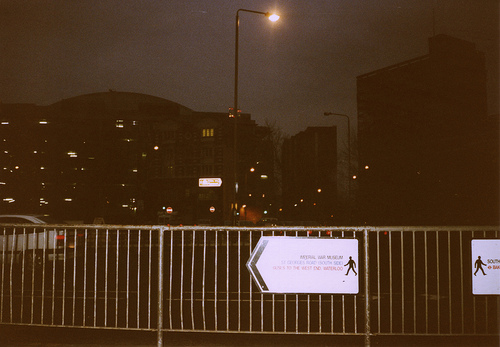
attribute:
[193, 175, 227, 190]
sign — red, white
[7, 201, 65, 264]
car parked — white colored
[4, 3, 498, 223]
sky — with clouds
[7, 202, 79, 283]
car — white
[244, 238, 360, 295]
sign — white, black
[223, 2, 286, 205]
light — lit up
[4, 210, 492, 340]
fencing — steel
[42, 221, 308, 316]
railing — metal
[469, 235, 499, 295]
sign — black, white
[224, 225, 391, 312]
sign — white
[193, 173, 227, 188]
sign — lit up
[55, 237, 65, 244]
light — danger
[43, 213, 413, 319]
metal fence — with sign on it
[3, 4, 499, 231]
city — at night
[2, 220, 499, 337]
railing — metal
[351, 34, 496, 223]
building — big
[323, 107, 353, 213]
street light — not lit up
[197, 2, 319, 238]
street light — thin, grey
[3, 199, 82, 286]
vehicle — white, parked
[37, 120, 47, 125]
light — on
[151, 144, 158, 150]
light — on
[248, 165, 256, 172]
light — on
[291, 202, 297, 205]
light — on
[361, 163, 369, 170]
light — on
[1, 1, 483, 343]
picture — dark